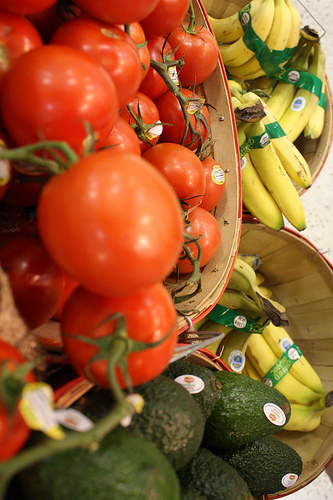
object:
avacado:
[136, 376, 203, 467]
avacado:
[211, 373, 290, 447]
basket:
[225, 5, 328, 178]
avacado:
[226, 433, 303, 495]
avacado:
[173, 373, 205, 393]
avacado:
[15, 434, 179, 498]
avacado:
[176, 447, 253, 498]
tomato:
[173, 204, 221, 275]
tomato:
[167, 21, 218, 87]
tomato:
[0, 236, 64, 328]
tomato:
[160, 20, 219, 90]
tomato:
[3, 41, 115, 152]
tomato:
[142, 141, 205, 211]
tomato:
[37, 132, 183, 293]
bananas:
[223, 252, 287, 330]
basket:
[124, 179, 327, 492]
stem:
[3, 130, 90, 168]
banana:
[246, 111, 308, 232]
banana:
[262, 318, 324, 394]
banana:
[253, 93, 312, 190]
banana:
[205, 1, 262, 42]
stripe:
[269, 64, 323, 99]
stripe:
[203, 307, 264, 337]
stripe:
[237, 30, 292, 77]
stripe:
[250, 128, 271, 150]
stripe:
[260, 341, 302, 388]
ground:
[319, 203, 330, 247]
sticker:
[262, 398, 287, 428]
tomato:
[198, 155, 225, 210]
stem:
[0, 372, 146, 468]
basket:
[242, 240, 333, 485]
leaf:
[125, 323, 187, 359]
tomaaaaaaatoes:
[71, 147, 204, 279]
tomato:
[155, 87, 211, 149]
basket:
[0, 0, 242, 333]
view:
[0, 0, 333, 491]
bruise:
[296, 169, 301, 176]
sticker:
[211, 163, 226, 186]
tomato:
[59, 282, 178, 387]